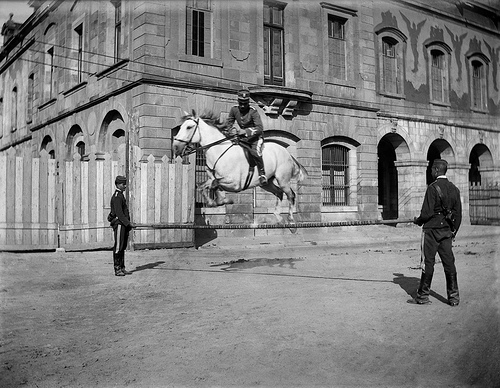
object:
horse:
[168, 109, 310, 234]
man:
[106, 175, 135, 277]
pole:
[131, 217, 421, 230]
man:
[405, 158, 462, 307]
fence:
[0, 152, 197, 253]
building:
[0, 0, 499, 250]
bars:
[193, 147, 224, 206]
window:
[170, 124, 228, 207]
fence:
[467, 181, 499, 225]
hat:
[234, 89, 251, 102]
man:
[221, 89, 267, 186]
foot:
[113, 259, 129, 278]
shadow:
[126, 259, 166, 273]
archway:
[376, 128, 413, 228]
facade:
[140, 0, 498, 248]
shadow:
[209, 257, 307, 274]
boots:
[411, 273, 435, 305]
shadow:
[147, 266, 394, 285]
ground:
[0, 226, 499, 388]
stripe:
[114, 224, 122, 254]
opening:
[425, 139, 457, 185]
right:
[0, 3, 256, 387]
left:
[228, 4, 498, 381]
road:
[0, 224, 499, 386]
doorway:
[466, 142, 493, 186]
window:
[382, 35, 396, 59]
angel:
[398, 11, 429, 74]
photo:
[0, 1, 499, 387]